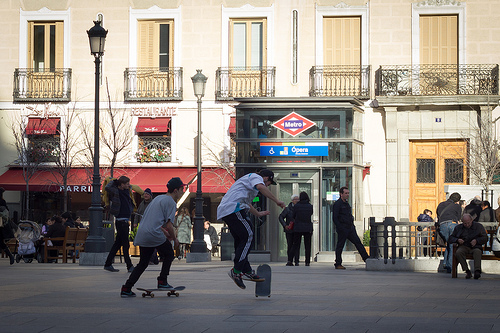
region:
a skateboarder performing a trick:
[218, 168, 288, 302]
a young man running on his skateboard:
[119, 175, 191, 302]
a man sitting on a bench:
[449, 212, 487, 282]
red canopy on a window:
[135, 115, 171, 132]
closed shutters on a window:
[321, 16, 363, 93]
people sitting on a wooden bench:
[37, 210, 87, 262]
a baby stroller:
[12, 219, 44, 264]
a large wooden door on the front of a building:
[411, 141, 468, 252]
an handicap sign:
[265, 145, 277, 155]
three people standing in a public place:
[276, 185, 368, 270]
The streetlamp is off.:
[76, 9, 115, 268]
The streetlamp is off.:
[178, 65, 220, 267]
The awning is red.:
[1, 160, 244, 269]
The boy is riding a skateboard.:
[118, 173, 200, 315]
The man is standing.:
[316, 175, 394, 280]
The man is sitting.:
[443, 205, 491, 292]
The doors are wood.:
[401, 125, 476, 275]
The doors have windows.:
[395, 123, 483, 278]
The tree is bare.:
[441, 100, 498, 274]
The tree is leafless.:
[446, 79, 498, 264]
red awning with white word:
[0, 165, 240, 192]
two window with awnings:
[22, 116, 169, 161]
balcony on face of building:
[310, 64, 371, 100]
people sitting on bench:
[45, 211, 86, 261]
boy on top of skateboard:
[120, 179, 187, 299]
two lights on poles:
[84, 21, 206, 264]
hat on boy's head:
[167, 176, 190, 201]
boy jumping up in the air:
[220, 167, 284, 299]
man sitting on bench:
[450, 214, 486, 279]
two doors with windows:
[412, 139, 468, 223]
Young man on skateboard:
[118, 175, 186, 305]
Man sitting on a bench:
[443, 209, 490, 280]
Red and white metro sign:
[267, 108, 320, 137]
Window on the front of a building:
[127, 5, 183, 106]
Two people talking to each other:
[278, 189, 316, 269]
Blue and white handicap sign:
[262, 144, 278, 156]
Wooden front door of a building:
[410, 134, 468, 259]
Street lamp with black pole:
[78, 17, 113, 267]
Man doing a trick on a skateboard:
[213, 160, 287, 299]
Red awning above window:
[135, 114, 172, 137]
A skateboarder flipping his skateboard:
[215, 165, 293, 302]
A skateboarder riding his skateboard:
[118, 175, 188, 297]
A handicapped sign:
[257, 140, 331, 158]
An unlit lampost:
[81, 18, 111, 267]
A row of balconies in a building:
[10, 12, 498, 106]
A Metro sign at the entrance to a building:
[268, 105, 317, 137]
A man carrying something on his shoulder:
[100, 171, 146, 277]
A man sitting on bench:
[445, 207, 498, 285]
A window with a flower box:
[130, 113, 177, 165]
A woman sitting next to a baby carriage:
[11, 213, 62, 267]